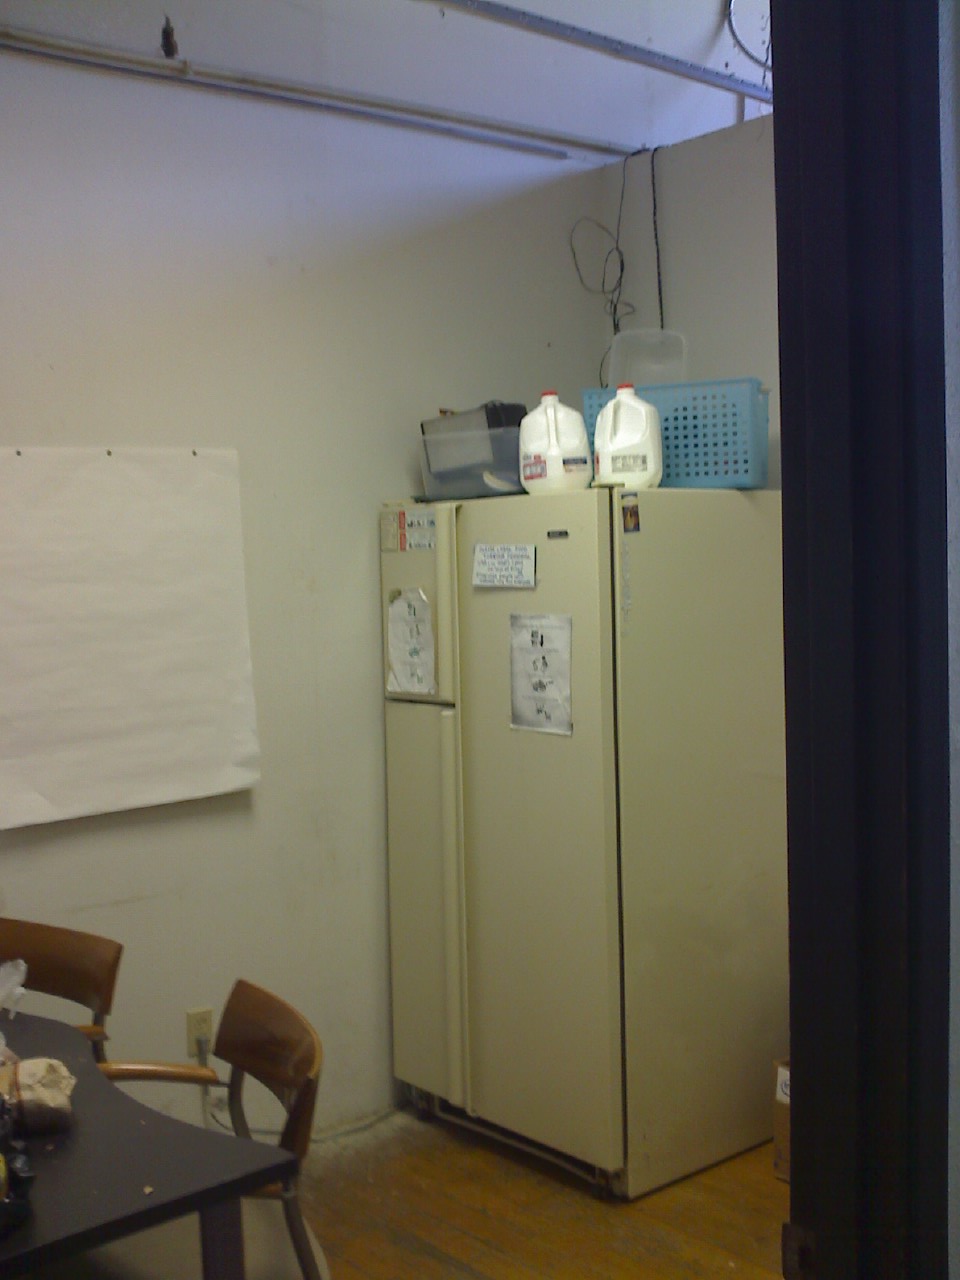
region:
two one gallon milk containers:
[511, 383, 671, 495]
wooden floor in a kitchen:
[46, 1101, 783, 1277]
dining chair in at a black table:
[90, 978, 331, 1276]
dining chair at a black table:
[2, 912, 125, 1062]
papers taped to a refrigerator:
[375, 534, 575, 736]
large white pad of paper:
[0, 438, 270, 834]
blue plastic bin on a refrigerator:
[581, 373, 774, 495]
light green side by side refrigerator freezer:
[373, 483, 785, 1208]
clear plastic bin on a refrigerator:
[407, 421, 531, 493]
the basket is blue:
[685, 409, 745, 467]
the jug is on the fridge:
[609, 451, 658, 511]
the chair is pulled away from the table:
[92, 963, 353, 1160]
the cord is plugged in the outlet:
[178, 1002, 223, 1063]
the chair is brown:
[44, 941, 86, 980]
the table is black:
[163, 1127, 224, 1173]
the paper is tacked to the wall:
[62, 433, 269, 534]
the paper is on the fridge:
[388, 580, 431, 669]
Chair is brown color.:
[218, 950, 349, 1266]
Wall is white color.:
[45, 246, 396, 957]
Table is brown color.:
[9, 1057, 247, 1275]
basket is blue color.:
[574, 357, 770, 496]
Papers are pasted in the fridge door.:
[384, 503, 589, 778]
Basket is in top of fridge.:
[523, 367, 773, 504]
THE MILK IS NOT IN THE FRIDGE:
[492, 379, 679, 503]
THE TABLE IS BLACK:
[4, 1009, 287, 1276]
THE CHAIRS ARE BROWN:
[0, 907, 379, 1275]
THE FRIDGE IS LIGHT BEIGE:
[355, 466, 788, 1210]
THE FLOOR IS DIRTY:
[156, 1072, 803, 1274]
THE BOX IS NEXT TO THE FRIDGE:
[733, 1050, 830, 1184]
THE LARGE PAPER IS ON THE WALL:
[0, 414, 266, 847]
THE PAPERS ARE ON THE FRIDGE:
[370, 490, 599, 756]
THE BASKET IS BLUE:
[556, 368, 796, 512]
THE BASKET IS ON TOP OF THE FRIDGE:
[569, 378, 777, 511]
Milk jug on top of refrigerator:
[519, 379, 590, 494]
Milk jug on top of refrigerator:
[590, 379, 690, 487]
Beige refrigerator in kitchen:
[357, 492, 787, 1191]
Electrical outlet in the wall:
[165, 1003, 233, 1068]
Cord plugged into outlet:
[168, 1041, 424, 1143]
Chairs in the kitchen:
[4, 928, 370, 1265]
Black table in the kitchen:
[3, 993, 323, 1260]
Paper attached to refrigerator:
[484, 608, 606, 776]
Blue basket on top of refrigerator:
[541, 358, 781, 515]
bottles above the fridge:
[417, 339, 722, 535]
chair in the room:
[183, 950, 420, 1183]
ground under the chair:
[342, 1111, 517, 1270]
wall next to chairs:
[178, 802, 361, 956]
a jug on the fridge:
[476, 393, 598, 537]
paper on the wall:
[35, 398, 454, 875]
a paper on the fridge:
[506, 611, 567, 734]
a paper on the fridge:
[474, 537, 567, 604]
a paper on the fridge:
[403, 549, 460, 735]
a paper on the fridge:
[407, 508, 446, 550]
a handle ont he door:
[426, 722, 495, 1051]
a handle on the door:
[417, 508, 492, 656]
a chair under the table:
[200, 974, 345, 1268]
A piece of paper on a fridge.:
[504, 607, 572, 733]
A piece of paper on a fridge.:
[394, 504, 448, 539]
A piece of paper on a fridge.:
[373, 577, 449, 693]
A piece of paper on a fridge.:
[617, 489, 633, 524]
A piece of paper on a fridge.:
[506, 613, 580, 735]